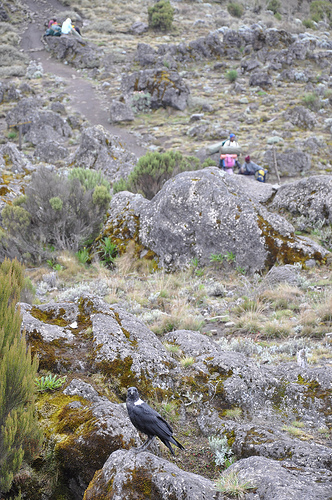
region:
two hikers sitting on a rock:
[41, 13, 89, 57]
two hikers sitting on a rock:
[210, 121, 273, 189]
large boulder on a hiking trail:
[147, 161, 268, 277]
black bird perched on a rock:
[114, 373, 191, 475]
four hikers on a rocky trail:
[36, 8, 284, 199]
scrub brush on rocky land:
[132, 275, 278, 321]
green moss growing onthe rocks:
[38, 303, 106, 361]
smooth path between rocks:
[61, 70, 134, 137]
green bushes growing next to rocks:
[134, 149, 172, 184]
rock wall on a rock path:
[129, 23, 284, 71]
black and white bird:
[124, 387, 180, 455]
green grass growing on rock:
[212, 472, 260, 499]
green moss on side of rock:
[29, 304, 117, 345]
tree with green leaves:
[127, 147, 170, 199]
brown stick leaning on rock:
[269, 141, 284, 184]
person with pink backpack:
[219, 152, 240, 172]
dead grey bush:
[38, 212, 84, 248]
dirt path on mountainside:
[70, 71, 109, 124]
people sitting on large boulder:
[39, 12, 88, 50]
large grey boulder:
[146, 175, 286, 283]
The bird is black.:
[118, 377, 180, 463]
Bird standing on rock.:
[121, 383, 183, 458]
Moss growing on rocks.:
[42, 387, 107, 469]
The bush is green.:
[0, 255, 43, 491]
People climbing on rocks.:
[207, 141, 281, 192]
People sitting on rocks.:
[43, 11, 81, 40]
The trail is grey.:
[8, 1, 267, 182]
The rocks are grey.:
[6, 3, 329, 498]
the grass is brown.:
[47, 237, 330, 343]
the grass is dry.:
[52, 245, 329, 350]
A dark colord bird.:
[118, 373, 188, 469]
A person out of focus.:
[220, 129, 240, 175]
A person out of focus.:
[243, 149, 268, 185]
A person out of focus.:
[61, 15, 78, 38]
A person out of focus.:
[41, 14, 62, 37]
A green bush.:
[90, 183, 111, 214]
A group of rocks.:
[127, 21, 287, 120]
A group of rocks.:
[67, 298, 229, 397]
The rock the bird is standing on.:
[78, 442, 225, 498]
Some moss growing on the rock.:
[27, 332, 77, 378]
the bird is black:
[69, 373, 218, 468]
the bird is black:
[120, 382, 192, 497]